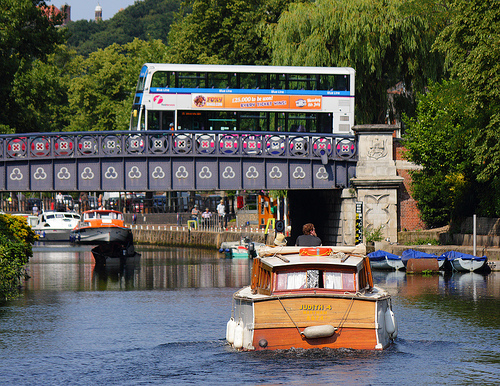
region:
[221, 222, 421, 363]
Boat in the water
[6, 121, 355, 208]
The bridge is grey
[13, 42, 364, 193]
A bus driving over the bridge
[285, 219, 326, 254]
Man on the boat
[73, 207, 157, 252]
The boat is white and orange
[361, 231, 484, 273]
Boats with blue tarps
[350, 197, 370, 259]
Tall and narrow sign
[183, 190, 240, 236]
People on the side walk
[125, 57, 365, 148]
The bus is white and blue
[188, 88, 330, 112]
Orange sign on side of bus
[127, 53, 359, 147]
a double decker bus on a bridge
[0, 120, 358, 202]
a bridge over a river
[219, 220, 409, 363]
a boat in a river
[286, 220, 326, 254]
a man stand on a boat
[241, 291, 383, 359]
back of boat is orange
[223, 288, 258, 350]
side of boat is white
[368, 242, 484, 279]
blue small boats on side a river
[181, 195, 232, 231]
people walking near the river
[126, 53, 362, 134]
roof of bus is white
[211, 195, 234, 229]
person wearing a white shirt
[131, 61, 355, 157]
A blue and white double decker bus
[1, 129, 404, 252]
A decorative blue-gray bridge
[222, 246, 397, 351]
A gold and white boat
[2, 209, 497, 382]
A river full of boats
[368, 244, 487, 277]
Three boats covered with blue tarps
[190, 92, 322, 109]
An orange ad on the side of a bus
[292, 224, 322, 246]
A person on a boat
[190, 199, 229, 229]
A group of three people looking over the river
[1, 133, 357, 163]
Railing with circles on a bridge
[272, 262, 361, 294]
Back windows of a boat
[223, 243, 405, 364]
small boat cruising down river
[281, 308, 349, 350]
Buoy on back of boat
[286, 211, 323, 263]
Man riding in boat down river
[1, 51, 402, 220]
Bus driving over bridge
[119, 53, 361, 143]
A double decker bus on bridge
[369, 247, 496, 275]
Boats with blue covers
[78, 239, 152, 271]
Small fishing boat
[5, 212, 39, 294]
Large bush on side of river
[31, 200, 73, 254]
White boat parked on river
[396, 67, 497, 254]
Large tree next to sidewalk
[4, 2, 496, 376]
A waterway scene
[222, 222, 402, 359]
A boat is on the water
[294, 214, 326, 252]
A man is sitting on the boat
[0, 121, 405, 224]
A bridge is over the water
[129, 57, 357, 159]
A bus is crossing the bridge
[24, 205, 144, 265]
Other boats are on the water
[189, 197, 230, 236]
People are standing here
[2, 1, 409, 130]
Trees are growing in the background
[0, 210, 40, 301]
Bushes are growing near the water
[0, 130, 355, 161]
A rail is on the bridge